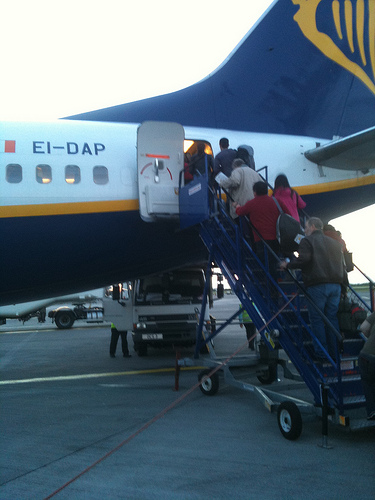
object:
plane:
[0, 0, 374, 311]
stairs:
[316, 375, 375, 401]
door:
[136, 120, 185, 224]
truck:
[102, 260, 224, 356]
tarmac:
[0, 286, 375, 500]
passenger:
[219, 158, 266, 256]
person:
[232, 179, 293, 310]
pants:
[109, 326, 130, 356]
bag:
[271, 194, 307, 256]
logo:
[289, 0, 375, 98]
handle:
[154, 157, 159, 184]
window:
[65, 164, 82, 184]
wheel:
[276, 400, 303, 442]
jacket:
[285, 229, 345, 289]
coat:
[270, 185, 307, 224]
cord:
[41, 287, 301, 500]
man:
[279, 215, 346, 365]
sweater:
[235, 192, 293, 243]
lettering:
[32, 139, 107, 156]